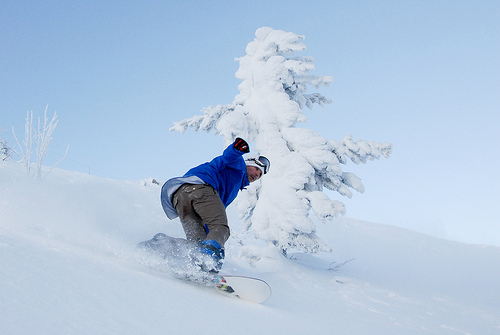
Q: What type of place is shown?
A: It is an ocean.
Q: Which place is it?
A: It is an ocean.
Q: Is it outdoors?
A: Yes, it is outdoors.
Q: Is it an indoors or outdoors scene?
A: It is outdoors.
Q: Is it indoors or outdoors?
A: It is outdoors.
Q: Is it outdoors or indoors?
A: It is outdoors.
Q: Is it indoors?
A: No, it is outdoors.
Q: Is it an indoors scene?
A: No, it is outdoors.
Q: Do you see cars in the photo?
A: No, there are no cars.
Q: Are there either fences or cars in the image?
A: No, there are no cars or fences.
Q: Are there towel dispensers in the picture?
A: No, there are no towel dispensers.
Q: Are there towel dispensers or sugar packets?
A: No, there are no towel dispensers or sugar packets.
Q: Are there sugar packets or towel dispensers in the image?
A: No, there are no towel dispensers or sugar packets.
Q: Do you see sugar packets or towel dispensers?
A: No, there are no towel dispensers or sugar packets.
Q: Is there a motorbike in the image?
A: No, there are no motorcycles.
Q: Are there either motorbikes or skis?
A: No, there are no motorbikes or skis.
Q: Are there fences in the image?
A: No, there are no fences.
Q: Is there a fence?
A: No, there are no fences.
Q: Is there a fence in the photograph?
A: No, there are no fences.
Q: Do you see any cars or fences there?
A: No, there are no fences or cars.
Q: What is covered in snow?
A: The tree is covered in snow.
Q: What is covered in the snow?
A: The tree is covered in snow.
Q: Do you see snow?
A: Yes, there is snow.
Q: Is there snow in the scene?
A: Yes, there is snow.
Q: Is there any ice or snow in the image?
A: Yes, there is snow.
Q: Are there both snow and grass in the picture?
A: No, there is snow but no grass.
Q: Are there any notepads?
A: No, there are no notepads.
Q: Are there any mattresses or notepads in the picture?
A: No, there are no notepads or mattresses.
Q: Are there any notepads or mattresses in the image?
A: No, there are no notepads or mattresses.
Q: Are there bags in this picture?
A: No, there are no bags.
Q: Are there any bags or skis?
A: No, there are no bags or skis.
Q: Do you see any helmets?
A: Yes, there is a helmet.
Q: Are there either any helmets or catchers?
A: Yes, there is a helmet.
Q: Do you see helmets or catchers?
A: Yes, there is a helmet.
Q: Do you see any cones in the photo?
A: No, there are no cones.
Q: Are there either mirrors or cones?
A: No, there are no cones or mirrors.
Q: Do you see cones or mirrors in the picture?
A: No, there are no cones or mirrors.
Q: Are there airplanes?
A: No, there are no airplanes.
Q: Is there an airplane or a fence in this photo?
A: No, there are no airplanes or fences.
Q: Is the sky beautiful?
A: Yes, the sky is beautiful.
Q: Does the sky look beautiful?
A: Yes, the sky is beautiful.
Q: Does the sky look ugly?
A: No, the sky is beautiful.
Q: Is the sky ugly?
A: No, the sky is beautiful.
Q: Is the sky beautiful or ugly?
A: The sky is beautiful.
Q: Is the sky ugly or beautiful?
A: The sky is beautiful.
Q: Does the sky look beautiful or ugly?
A: The sky is beautiful.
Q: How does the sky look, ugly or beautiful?
A: The sky is beautiful.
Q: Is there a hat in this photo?
A: Yes, there is a hat.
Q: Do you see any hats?
A: Yes, there is a hat.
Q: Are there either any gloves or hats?
A: Yes, there is a hat.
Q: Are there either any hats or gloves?
A: Yes, there is a hat.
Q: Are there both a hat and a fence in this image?
A: No, there is a hat but no fences.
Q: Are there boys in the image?
A: No, there are no boys.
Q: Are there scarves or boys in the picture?
A: No, there are no boys or scarves.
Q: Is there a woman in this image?
A: No, there are no women.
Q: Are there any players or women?
A: No, there are no women or players.